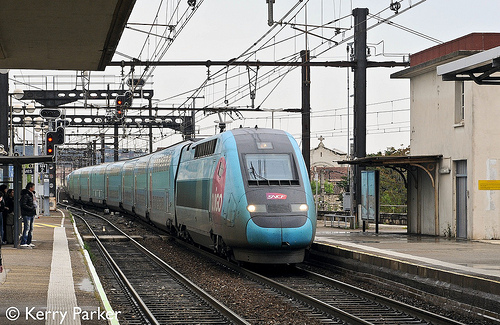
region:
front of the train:
[206, 110, 357, 260]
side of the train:
[55, 148, 230, 223]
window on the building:
[427, 63, 473, 162]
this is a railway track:
[152, 270, 162, 323]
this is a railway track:
[384, 285, 417, 303]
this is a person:
[24, 183, 41, 245]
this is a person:
[0, 186, 10, 208]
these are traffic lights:
[44, 135, 62, 157]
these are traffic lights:
[113, 100, 130, 120]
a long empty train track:
[54, 201, 249, 323]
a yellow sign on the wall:
[474, 178, 499, 190]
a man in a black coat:
[13, 178, 42, 250]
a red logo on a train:
[208, 157, 229, 222]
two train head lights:
[246, 202, 310, 217]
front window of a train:
[239, 148, 301, 189]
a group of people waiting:
[1, 181, 39, 249]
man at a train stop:
[16, 181, 40, 249]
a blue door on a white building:
[448, 153, 473, 243]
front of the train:
[216, 121, 335, 251]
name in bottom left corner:
[8, 290, 164, 323]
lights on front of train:
[232, 181, 321, 231]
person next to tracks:
[11, 159, 68, 244]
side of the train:
[72, 138, 229, 230]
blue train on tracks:
[52, 112, 325, 268]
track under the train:
[274, 268, 372, 313]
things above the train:
[108, 7, 369, 104]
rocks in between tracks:
[218, 276, 281, 318]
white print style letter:
[22, 302, 39, 320]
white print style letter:
[33, 307, 43, 321]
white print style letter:
[51, 308, 61, 318]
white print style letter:
[57, 309, 69, 321]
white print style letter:
[71, 305, 82, 320]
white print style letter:
[80, 310, 86, 320]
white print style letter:
[89, 307, 98, 322]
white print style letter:
[96, 306, 106, 321]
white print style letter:
[106, 310, 115, 322]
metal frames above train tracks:
[10, 0, 435, 322]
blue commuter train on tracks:
[68, 127, 454, 322]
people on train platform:
[2, 181, 122, 323]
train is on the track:
[64, 125, 318, 270]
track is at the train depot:
[63, 201, 249, 322]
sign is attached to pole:
[356, 168, 380, 220]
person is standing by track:
[21, 180, 38, 245]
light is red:
[46, 130, 56, 155]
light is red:
[114, 96, 124, 119]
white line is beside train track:
[44, 225, 81, 323]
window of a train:
[241, 151, 294, 186]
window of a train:
[193, 160, 214, 208]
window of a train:
[147, 167, 172, 194]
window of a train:
[133, 172, 147, 192]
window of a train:
[108, 176, 119, 188]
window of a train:
[91, 174, 103, 187]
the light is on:
[247, 201, 259, 211]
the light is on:
[297, 204, 307, 214]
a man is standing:
[22, 179, 39, 246]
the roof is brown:
[408, 32, 498, 60]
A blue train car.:
[176, 127, 320, 265]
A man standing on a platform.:
[13, 180, 40, 247]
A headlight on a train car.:
[247, 199, 269, 216]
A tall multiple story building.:
[388, 31, 496, 239]